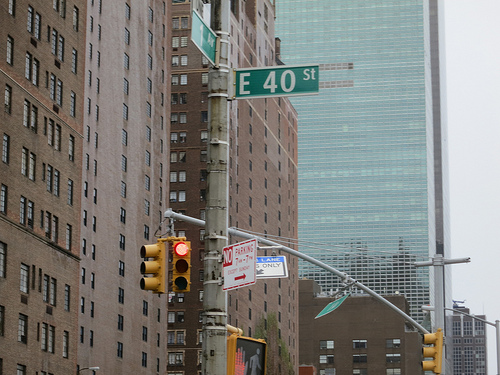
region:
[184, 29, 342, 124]
green and white street sign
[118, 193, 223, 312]
street light on red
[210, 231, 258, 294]
white and red parking sign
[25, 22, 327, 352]
tall brick building with many windows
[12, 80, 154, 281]
small rectangular windows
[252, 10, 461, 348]
skyscraper with glass windows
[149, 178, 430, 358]
light grey streetlight pole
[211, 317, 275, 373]
stop or walk pedestrain sign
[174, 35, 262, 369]
metal grey streetsign pole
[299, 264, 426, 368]
short brown building with windows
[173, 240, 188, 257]
the light is red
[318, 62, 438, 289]
the building is tall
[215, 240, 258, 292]
the sign is red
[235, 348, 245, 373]
the hand is red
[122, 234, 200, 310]
the lattern is yellow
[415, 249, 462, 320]
the pole is silver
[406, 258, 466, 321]
the pole is metal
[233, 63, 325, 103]
the sign is green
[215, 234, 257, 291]
the sign is rectangular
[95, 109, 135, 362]
the building is brown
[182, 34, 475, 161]
a green street sign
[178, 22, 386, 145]
a green street sign in the air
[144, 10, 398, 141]
two green street signs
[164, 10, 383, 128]
street signs on a pole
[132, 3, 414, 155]
street signs on a metal pole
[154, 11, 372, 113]
street signs on a tall pole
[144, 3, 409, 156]
signs on a pole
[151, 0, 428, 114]
signs in the air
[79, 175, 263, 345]
a red traffic light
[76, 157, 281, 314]
traffic lights on a pole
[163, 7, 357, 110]
two green and white street signs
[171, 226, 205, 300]
street light is red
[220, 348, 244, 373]
red hand in the street light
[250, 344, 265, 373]
white person on the street light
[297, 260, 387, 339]
wind moving the street sign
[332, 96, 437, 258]
building made of windows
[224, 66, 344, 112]
E 40 St written on street sign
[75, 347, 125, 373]
street light in front of buildings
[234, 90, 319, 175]
white line on the building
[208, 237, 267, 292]
red and white street sign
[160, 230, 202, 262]
The traffic light is red.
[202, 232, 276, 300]
A no parking sign is visible.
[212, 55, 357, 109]
The street sign reads E 40 St.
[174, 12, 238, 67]
A second street sign is visible.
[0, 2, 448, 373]
Buildings are in the background.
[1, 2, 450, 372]
The buildings are tall.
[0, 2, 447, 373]
The buildings have several windows.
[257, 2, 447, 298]
The building is made of glass.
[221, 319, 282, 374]
A walking signal is visible.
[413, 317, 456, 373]
A second traffic light is visible.